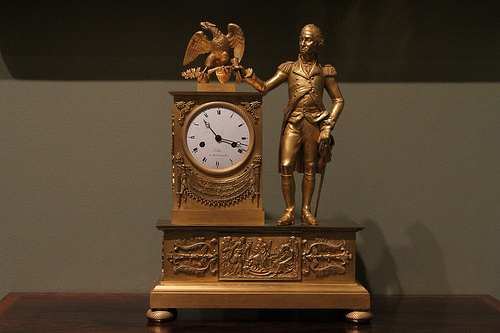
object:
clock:
[183, 101, 248, 179]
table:
[1, 291, 499, 332]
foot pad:
[144, 308, 173, 320]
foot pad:
[344, 310, 374, 320]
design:
[165, 236, 218, 277]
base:
[149, 226, 371, 310]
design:
[216, 231, 301, 281]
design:
[301, 238, 354, 280]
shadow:
[367, 226, 400, 296]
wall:
[0, 82, 499, 294]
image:
[240, 22, 345, 226]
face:
[186, 108, 251, 170]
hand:
[203, 119, 223, 142]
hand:
[214, 135, 249, 147]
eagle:
[181, 21, 244, 80]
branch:
[183, 67, 238, 78]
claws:
[204, 74, 207, 77]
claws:
[222, 67, 224, 71]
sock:
[281, 175, 296, 211]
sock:
[301, 174, 316, 206]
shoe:
[276, 213, 295, 226]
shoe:
[300, 211, 318, 226]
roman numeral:
[216, 109, 222, 115]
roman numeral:
[238, 123, 244, 127]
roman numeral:
[237, 148, 243, 153]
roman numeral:
[200, 157, 208, 164]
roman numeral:
[188, 135, 195, 139]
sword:
[312, 139, 331, 218]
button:
[311, 77, 314, 80]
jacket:
[244, 53, 345, 174]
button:
[307, 80, 311, 82]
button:
[309, 86, 312, 88]